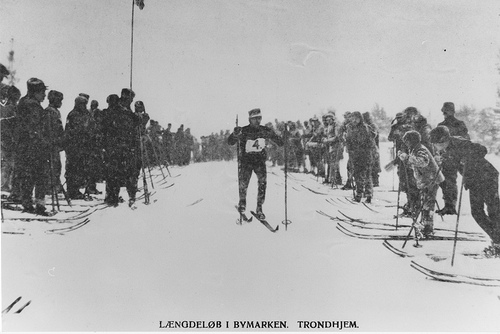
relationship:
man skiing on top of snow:
[234, 106, 280, 226] [186, 233, 352, 303]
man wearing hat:
[228, 108, 285, 206] [245, 106, 261, 118]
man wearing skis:
[228, 108, 285, 206] [233, 202, 285, 230]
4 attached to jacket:
[252, 140, 260, 150] [228, 124, 285, 164]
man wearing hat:
[228, 108, 285, 206] [242, 99, 269, 122]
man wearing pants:
[228, 108, 285, 206] [229, 157, 283, 230]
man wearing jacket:
[228, 108, 285, 206] [221, 119, 294, 169]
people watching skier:
[275, 100, 478, 294] [215, 87, 306, 257]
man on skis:
[228, 108, 285, 206] [229, 120, 303, 232]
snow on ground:
[44, 209, 459, 313] [43, 170, 467, 326]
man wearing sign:
[228, 108, 285, 206] [240, 130, 271, 158]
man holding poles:
[228, 108, 285, 206] [231, 121, 301, 235]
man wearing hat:
[228, 108, 285, 206] [247, 101, 260, 123]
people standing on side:
[269, 111, 484, 253] [261, 0, 482, 328]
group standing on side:
[0, 64, 161, 217] [4, 48, 194, 261]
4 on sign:
[251, 140, 259, 150] [240, 131, 269, 155]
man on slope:
[228, 108, 285, 206] [174, 141, 353, 331]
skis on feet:
[231, 178, 286, 247] [225, 199, 270, 217]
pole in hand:
[269, 105, 310, 239] [277, 124, 299, 150]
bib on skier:
[239, 132, 269, 164] [212, 69, 313, 264]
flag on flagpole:
[126, 1, 158, 18] [120, 2, 167, 192]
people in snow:
[265, 111, 382, 203] [180, 145, 483, 329]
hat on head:
[244, 99, 270, 119] [242, 109, 279, 137]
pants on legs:
[235, 159, 275, 214] [241, 160, 278, 223]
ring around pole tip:
[281, 217, 291, 225] [285, 225, 289, 230]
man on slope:
[228, 108, 285, 206] [3, 161, 496, 331]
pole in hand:
[285, 121, 289, 231] [281, 129, 293, 139]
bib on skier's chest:
[239, 132, 269, 164] [244, 130, 267, 152]